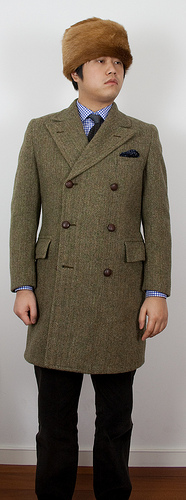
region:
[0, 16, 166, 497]
man with medium colored skin dressed for a cold day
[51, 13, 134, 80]
large brown hat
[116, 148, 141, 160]
black hankie hanging out of top right coat pocket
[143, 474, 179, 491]
wooden floor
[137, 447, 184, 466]
white baseboard against a white wall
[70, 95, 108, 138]
blue checkered shirt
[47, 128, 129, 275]
medium brown tweed coat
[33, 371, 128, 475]
black pants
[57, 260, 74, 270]
button hole with no button on the brown tweed coat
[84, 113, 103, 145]
dark tie against the blue checkered shirt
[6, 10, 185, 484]
An Asian man modeling an outfit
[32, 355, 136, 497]
Dark brown loose pants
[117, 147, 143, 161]
A black pocket square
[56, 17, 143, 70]
A light brown kubanka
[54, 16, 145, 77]
A light brown cylindrical faux fur cap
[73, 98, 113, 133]
A blue and white gingham dress shirt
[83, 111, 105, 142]
A black tie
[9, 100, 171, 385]
A greyish brown wool peacoat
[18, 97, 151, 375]
A double-breasted peacoat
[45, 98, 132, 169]
Large lapels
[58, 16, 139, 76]
A large fur hat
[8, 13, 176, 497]
A young man dressed for cold weather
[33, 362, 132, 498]
a pair of black pants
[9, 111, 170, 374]
A beige over coat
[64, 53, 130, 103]
The face of a young man of Asian descent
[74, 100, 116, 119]
Collar of a blue and white plaid shirt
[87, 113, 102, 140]
Dark colored neck tie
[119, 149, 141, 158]
Dark pocket handkerchief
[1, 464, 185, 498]
Stained hard wood floor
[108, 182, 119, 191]
Dark brown coat button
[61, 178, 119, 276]
The buttons on the jacket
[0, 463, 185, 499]
The wood floor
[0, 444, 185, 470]
The baseboard of the wall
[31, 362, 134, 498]
The man's black pants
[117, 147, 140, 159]
The handkerchief in the pocket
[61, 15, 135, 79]
The large brown hat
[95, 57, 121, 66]
The eyes of the man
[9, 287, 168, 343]
The man's hands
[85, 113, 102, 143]
The man's tie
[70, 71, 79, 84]
The man's right ear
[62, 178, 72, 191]
a button on a jacket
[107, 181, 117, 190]
a button on a jacket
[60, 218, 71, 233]
a button on a jacket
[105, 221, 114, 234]
a button on a jacket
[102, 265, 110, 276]
a button on a jacket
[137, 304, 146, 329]
the finger of a person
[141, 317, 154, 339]
the finger of a person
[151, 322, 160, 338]
the finger of a person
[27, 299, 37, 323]
the finger of a person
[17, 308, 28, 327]
the finger of a person